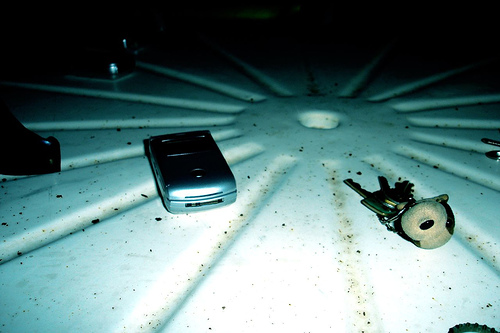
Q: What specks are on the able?
A: Dirt.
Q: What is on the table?
A: Cell phone.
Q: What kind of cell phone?
A: Flip phone.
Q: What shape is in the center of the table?
A: Circle.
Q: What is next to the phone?
A: Keys.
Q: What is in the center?
A: Flat ring.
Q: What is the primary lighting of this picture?
A: Dark.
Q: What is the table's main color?
A: White.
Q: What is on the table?
A: A phone.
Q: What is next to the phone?
A: A keychain.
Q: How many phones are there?
A: One.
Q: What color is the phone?
A: Silver.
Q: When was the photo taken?
A: Night time.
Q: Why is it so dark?
A: Lights are off.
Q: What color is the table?
A: White.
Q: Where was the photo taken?
A: In a house.